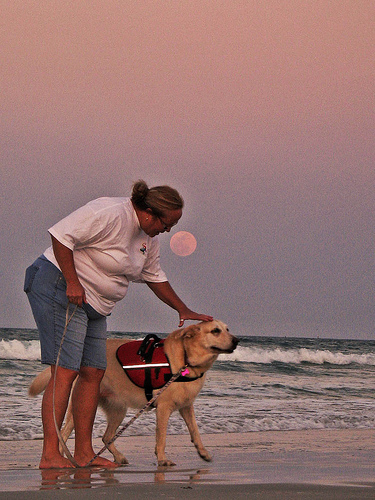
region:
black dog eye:
[210, 326, 222, 335]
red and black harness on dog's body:
[112, 333, 169, 402]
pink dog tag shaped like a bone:
[179, 365, 189, 377]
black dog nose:
[229, 334, 239, 343]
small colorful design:
[139, 239, 148, 254]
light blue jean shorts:
[24, 254, 108, 369]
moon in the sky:
[170, 230, 200, 262]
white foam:
[239, 347, 374, 363]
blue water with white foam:
[241, 337, 374, 426]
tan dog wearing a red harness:
[106, 320, 240, 465]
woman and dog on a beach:
[11, 138, 248, 480]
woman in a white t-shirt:
[16, 131, 180, 475]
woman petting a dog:
[13, 176, 250, 482]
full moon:
[165, 228, 199, 258]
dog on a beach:
[120, 311, 264, 481]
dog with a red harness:
[110, 324, 242, 473]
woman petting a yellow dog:
[6, 136, 248, 498]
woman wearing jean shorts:
[25, 148, 187, 495]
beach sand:
[255, 438, 367, 495]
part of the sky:
[204, 53, 251, 106]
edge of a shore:
[247, 422, 295, 458]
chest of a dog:
[184, 391, 198, 417]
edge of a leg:
[75, 446, 110, 467]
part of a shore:
[280, 447, 318, 485]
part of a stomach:
[113, 379, 129, 392]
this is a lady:
[28, 141, 157, 407]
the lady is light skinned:
[76, 387, 93, 418]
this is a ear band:
[144, 213, 151, 222]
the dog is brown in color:
[192, 337, 215, 366]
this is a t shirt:
[100, 230, 128, 299]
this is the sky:
[207, 134, 368, 322]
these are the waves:
[252, 341, 304, 363]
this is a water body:
[258, 354, 337, 414]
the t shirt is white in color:
[87, 244, 108, 277]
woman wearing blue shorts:
[7, 252, 107, 365]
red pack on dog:
[114, 335, 177, 397]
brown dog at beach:
[165, 321, 239, 459]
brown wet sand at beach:
[224, 437, 364, 480]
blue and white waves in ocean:
[249, 337, 370, 383]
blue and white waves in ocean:
[213, 371, 356, 417]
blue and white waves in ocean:
[4, 330, 29, 433]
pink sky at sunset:
[13, 10, 360, 169]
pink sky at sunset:
[183, 110, 360, 283]